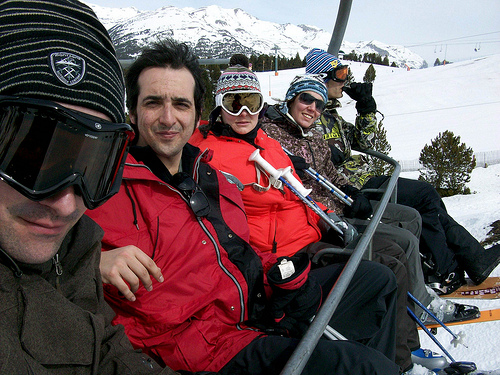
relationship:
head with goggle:
[6, 10, 146, 295] [2, 77, 137, 221]